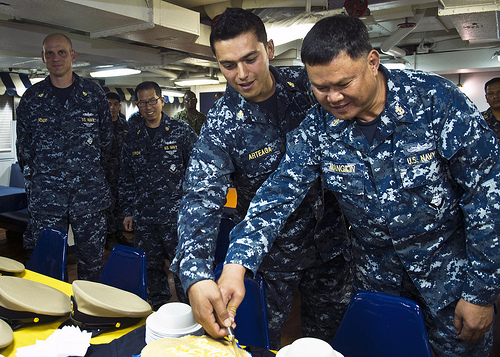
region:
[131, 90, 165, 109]
man is wearing a pair of glasses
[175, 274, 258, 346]
men are cutting a cake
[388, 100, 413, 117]
rank insignia for the navy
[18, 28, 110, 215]
man standing with his hands behind his back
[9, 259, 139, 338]
military hats on the table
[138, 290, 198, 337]
small white bowls by the table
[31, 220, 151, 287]
chairs are blue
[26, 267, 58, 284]
table is yellow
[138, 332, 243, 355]
cake on the table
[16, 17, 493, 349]
soldiers in uniform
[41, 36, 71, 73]
the head on a person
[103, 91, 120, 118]
the head on a person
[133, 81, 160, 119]
the head on a person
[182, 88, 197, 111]
the head on a person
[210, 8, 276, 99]
the head on a person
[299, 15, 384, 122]
the head on a person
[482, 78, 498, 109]
the head on a person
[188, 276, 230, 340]
the hand of a person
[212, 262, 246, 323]
the hand of a person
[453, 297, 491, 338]
the hand of a person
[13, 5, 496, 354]
Men in navy uniforms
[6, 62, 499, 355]
Men are wearing blue uniforms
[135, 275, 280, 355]
Men are cutting a cake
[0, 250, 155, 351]
Hats are on the table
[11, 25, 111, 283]
Man is looking at the camera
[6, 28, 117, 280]
Man in the background is bald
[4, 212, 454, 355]
The chairs are dark blue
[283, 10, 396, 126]
Man is looking down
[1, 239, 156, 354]
The hats are tan in color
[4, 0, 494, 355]
Photo was taken indoors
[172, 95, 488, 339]
soldiers are wearing uniforms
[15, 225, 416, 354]
the chairs are blue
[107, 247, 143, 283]
blue color chair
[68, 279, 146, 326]
white cap kept on table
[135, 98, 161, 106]
man wearing specs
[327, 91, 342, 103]
Nose of the man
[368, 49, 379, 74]
ear of the man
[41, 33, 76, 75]
man with bald head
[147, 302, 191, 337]
thermocol bowl kept on table